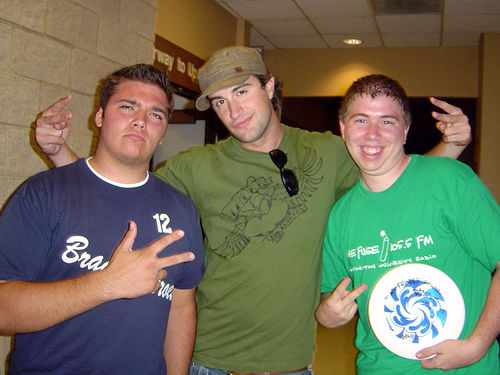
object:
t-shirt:
[0, 158, 208, 373]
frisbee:
[366, 261, 465, 362]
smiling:
[343, 131, 403, 171]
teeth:
[363, 146, 382, 156]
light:
[343, 38, 363, 45]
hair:
[98, 63, 175, 119]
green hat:
[196, 45, 267, 111]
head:
[197, 45, 284, 142]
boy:
[33, 45, 472, 374]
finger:
[429, 97, 462, 114]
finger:
[432, 111, 462, 123]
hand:
[108, 219, 197, 299]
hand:
[427, 96, 471, 146]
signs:
[383, 279, 451, 343]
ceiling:
[217, 2, 500, 50]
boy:
[313, 73, 499, 374]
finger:
[341, 283, 369, 306]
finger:
[332, 275, 351, 299]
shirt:
[319, 153, 500, 374]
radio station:
[347, 229, 434, 262]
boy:
[0, 62, 205, 374]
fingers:
[154, 251, 196, 270]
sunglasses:
[268, 149, 299, 198]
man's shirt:
[153, 124, 364, 374]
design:
[213, 146, 324, 262]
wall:
[0, 1, 156, 174]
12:
[152, 213, 173, 234]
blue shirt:
[0, 157, 206, 375]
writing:
[60, 235, 176, 302]